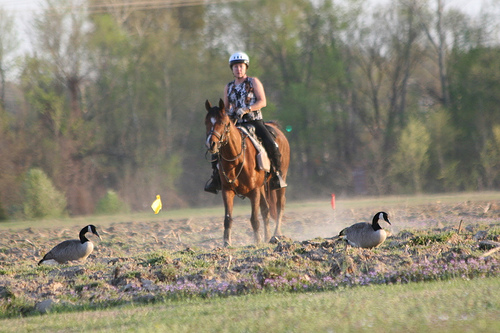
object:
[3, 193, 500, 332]
field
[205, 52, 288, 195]
woman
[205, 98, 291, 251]
horse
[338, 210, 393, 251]
bird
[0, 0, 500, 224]
trees